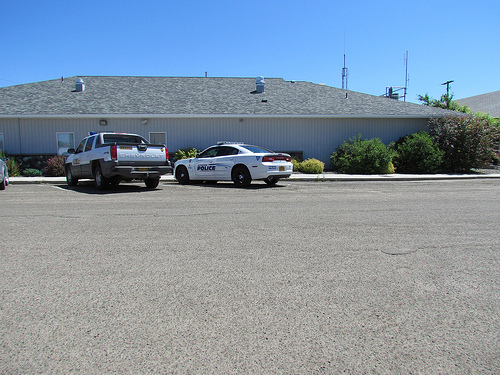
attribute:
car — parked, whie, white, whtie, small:
[174, 143, 293, 192]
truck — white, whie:
[51, 125, 180, 200]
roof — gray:
[133, 76, 157, 98]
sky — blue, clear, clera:
[210, 17, 211, 21]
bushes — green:
[342, 144, 376, 157]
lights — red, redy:
[101, 142, 122, 167]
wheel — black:
[90, 167, 109, 182]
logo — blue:
[186, 161, 226, 178]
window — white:
[51, 122, 76, 145]